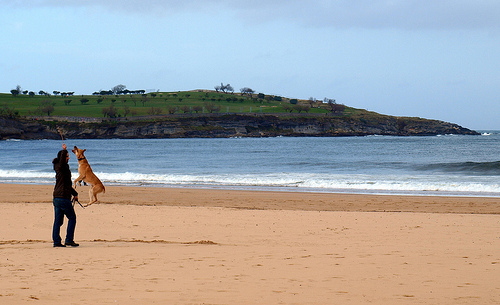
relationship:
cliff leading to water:
[0, 90, 475, 140] [0, 133, 500, 200]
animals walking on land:
[6, 87, 151, 98] [0, 87, 483, 140]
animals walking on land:
[71, 145, 106, 207] [0, 177, 498, 302]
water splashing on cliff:
[482, 129, 498, 140] [2, 86, 479, 141]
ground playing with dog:
[426, 177, 458, 206] [70, 140, 112, 202]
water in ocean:
[0, 129, 499, 197] [154, 131, 496, 185]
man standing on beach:
[49, 143, 78, 247] [0, 151, 498, 249]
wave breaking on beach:
[1, 162, 497, 192] [124, 141, 467, 299]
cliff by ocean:
[0, 88, 482, 140] [77, 144, 497, 194]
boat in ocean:
[478, 130, 491, 137] [0, 130, 499, 187]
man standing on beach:
[49, 143, 78, 247] [3, 180, 498, 300]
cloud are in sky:
[0, 0, 494, 132] [295, 28, 455, 93]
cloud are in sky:
[0, 0, 494, 132] [394, 31, 483, 91]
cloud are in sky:
[0, 0, 494, 132] [0, 2, 495, 124]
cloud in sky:
[0, 0, 494, 132] [0, 2, 495, 124]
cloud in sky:
[5, 15, 497, 132] [0, 2, 495, 124]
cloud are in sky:
[0, 0, 494, 132] [72, 25, 140, 66]